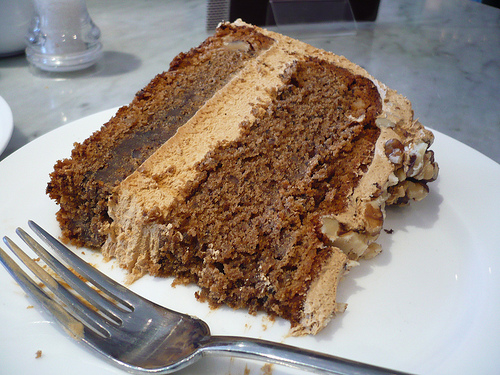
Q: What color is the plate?
A: White.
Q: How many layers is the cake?
A: Two.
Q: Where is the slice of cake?
A: On the plate.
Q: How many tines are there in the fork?
A: Four.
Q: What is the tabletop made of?
A: Marble.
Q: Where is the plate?
A: On the table.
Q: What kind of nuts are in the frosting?
A: Walnut.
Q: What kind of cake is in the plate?
A: Chocolate.